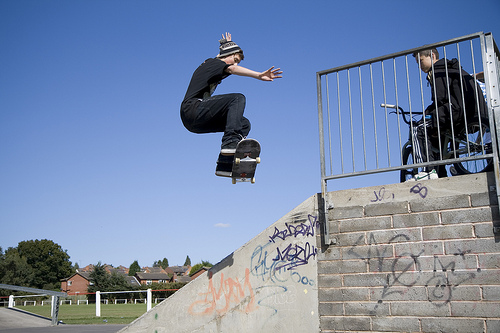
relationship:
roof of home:
[136, 262, 176, 280] [134, 269, 170, 300]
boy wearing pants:
[179, 32, 283, 183] [179, 90, 251, 145]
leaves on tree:
[28, 241, 54, 266] [3, 236, 73, 302]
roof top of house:
[74, 263, 97, 288] [129, 264, 174, 290]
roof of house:
[136, 272, 170, 279] [54, 261, 94, 305]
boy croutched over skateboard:
[180, 43, 283, 177] [226, 130, 258, 195]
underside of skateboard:
[224, 140, 256, 177] [222, 137, 272, 187]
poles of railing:
[324, 40, 480, 174] [287, 47, 498, 182]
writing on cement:
[238, 214, 318, 305] [122, 190, 320, 331]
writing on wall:
[351, 237, 482, 319] [198, 196, 499, 321]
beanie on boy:
[219, 32, 243, 58] [180, 43, 283, 177]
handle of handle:
[374, 94, 398, 111] [380, 103, 396, 108]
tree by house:
[3, 234, 71, 306] [50, 256, 194, 303]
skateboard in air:
[232, 138, 261, 178] [7, 0, 498, 301]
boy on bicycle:
[403, 48, 470, 184] [377, 94, 498, 174]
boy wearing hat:
[180, 43, 283, 177] [215, 33, 242, 55]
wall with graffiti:
[320, 171, 498, 331] [348, 239, 466, 323]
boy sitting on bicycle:
[403, 48, 470, 184] [377, 101, 492, 183]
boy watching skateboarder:
[406, 44, 489, 174] [174, 29, 290, 191]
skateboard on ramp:
[227, 141, 265, 194] [128, 189, 326, 331]